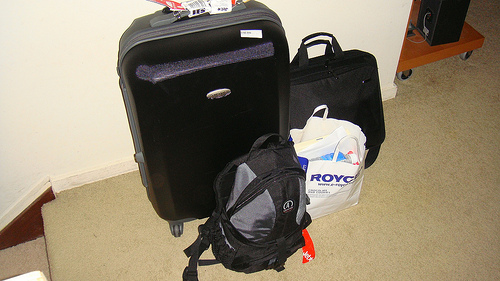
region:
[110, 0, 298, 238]
a black and grey suitcase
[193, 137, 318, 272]
a black and grey backpack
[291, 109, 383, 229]
a white and blue bag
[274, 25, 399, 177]
a black hand bag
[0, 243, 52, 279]
a white carpeted stair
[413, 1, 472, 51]
a black speaker on a cart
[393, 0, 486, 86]
a brown wooden cart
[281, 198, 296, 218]
a logo on a backpack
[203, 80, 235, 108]
a silver emblem on a suitcase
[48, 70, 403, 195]
white wall molding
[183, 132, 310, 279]
A black strap backpack with some silver patches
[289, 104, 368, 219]
A white paper bag with something in it.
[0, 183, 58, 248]
Some wood on the side of the stairwell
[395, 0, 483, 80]
A wooden dolly or table with wheels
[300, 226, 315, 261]
An orange backpack tag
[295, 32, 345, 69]
The handle of a computer bag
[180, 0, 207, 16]
A bag sticker for a flight.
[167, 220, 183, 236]
A suitcase wheel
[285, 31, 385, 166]
A black computer bag next to the suitcase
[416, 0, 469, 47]
A stereo speaker on a dolly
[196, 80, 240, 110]
silver plaque on bag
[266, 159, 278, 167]
black color on bookbag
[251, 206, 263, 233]
grey color on bookbag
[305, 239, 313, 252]
orange tag on bookbag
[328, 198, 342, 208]
white bag on floor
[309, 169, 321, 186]
letter r on bag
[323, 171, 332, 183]
letter o on bag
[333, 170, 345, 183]
letter y on bag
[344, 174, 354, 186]
letter c on bag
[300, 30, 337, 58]
handles on black bag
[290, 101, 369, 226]
paper tote bag full of trash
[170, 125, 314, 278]
black and grey backpack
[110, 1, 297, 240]
black hard rolling suitcase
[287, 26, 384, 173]
short handled computer bag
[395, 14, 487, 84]
rolling entertainment center block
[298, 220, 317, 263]
red airport tag on backpack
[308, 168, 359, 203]
advertisement label printed on bag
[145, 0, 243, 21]
identification stickers on suitcase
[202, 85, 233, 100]
silver manufacturer button on suitcase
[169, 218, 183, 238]
small black wheels on suitcase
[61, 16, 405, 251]
many items in the photo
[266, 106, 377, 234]
white bag in photo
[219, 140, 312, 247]
black and gray backpack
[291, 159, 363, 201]
word on the bag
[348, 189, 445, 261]
ground under the luggage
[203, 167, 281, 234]
zipper on the bag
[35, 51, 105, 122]
wall next to luggage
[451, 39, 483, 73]
wheel on an object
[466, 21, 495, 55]
corner of an object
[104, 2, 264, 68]
top of the luggage